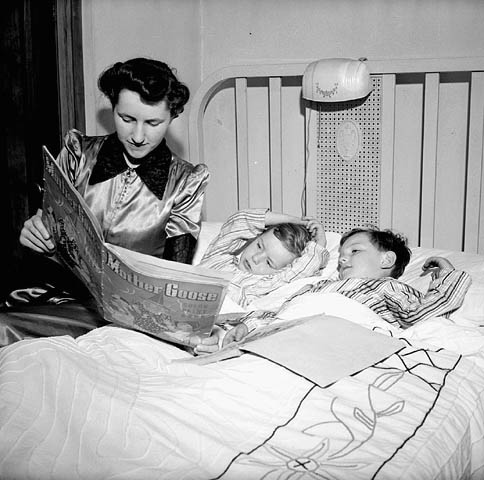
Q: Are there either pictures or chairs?
A: No, there are no chairs or pictures.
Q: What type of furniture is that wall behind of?
A: The wall is behind the bed.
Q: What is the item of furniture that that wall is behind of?
A: The piece of furniture is a bed.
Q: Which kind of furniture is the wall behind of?
A: The wall is behind the bed.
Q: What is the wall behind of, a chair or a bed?
A: The wall is behind a bed.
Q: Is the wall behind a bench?
A: No, the wall is behind a bed.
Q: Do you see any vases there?
A: No, there are no vases.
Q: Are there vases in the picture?
A: No, there are no vases.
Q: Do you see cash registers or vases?
A: No, there are no vases or cash registers.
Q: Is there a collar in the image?
A: Yes, there is a collar.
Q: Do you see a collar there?
A: Yes, there is a collar.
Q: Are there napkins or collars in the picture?
A: Yes, there is a collar.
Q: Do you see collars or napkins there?
A: Yes, there is a collar.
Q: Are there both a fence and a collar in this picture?
A: No, there is a collar but no fences.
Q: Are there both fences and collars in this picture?
A: No, there is a collar but no fences.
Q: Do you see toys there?
A: No, there are no toys.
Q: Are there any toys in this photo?
A: No, there are no toys.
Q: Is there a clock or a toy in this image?
A: No, there are no toys or clocks.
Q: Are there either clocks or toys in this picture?
A: No, there are no toys or clocks.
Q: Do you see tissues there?
A: No, there are no tissues.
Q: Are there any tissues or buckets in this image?
A: No, there are no tissues or buckets.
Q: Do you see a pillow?
A: Yes, there is a pillow.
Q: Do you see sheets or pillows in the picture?
A: Yes, there is a pillow.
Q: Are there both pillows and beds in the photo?
A: Yes, there are both a pillow and a bed.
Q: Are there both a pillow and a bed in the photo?
A: Yes, there are both a pillow and a bed.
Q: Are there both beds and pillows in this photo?
A: Yes, there are both a pillow and a bed.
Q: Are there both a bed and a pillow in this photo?
A: Yes, there are both a pillow and a bed.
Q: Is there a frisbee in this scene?
A: No, there are no frisbees.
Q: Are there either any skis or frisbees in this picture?
A: No, there are no frisbees or skis.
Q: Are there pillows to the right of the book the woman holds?
A: Yes, there is a pillow to the right of the book.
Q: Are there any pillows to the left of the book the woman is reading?
A: No, the pillow is to the right of the book.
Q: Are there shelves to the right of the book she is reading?
A: No, there is a pillow to the right of the book.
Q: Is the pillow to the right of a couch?
A: No, the pillow is to the right of the book.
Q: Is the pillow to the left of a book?
A: No, the pillow is to the right of a book.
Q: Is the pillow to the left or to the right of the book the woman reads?
A: The pillow is to the right of the book.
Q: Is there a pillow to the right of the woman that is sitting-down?
A: Yes, there is a pillow to the right of the woman.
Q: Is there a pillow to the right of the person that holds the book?
A: Yes, there is a pillow to the right of the woman.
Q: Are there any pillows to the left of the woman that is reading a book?
A: No, the pillow is to the right of the woman.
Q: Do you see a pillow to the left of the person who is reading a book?
A: No, the pillow is to the right of the woman.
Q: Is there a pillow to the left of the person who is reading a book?
A: No, the pillow is to the right of the woman.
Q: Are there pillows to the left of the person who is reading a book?
A: No, the pillow is to the right of the woman.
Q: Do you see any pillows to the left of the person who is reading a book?
A: No, the pillow is to the right of the woman.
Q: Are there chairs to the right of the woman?
A: No, there is a pillow to the right of the woman.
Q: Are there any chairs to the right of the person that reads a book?
A: No, there is a pillow to the right of the woman.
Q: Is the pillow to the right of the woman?
A: Yes, the pillow is to the right of the woman.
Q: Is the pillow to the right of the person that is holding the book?
A: Yes, the pillow is to the right of the woman.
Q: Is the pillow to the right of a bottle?
A: No, the pillow is to the right of the woman.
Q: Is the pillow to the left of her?
A: No, the pillow is to the right of the woman.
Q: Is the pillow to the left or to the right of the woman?
A: The pillow is to the right of the woman.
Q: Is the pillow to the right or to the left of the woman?
A: The pillow is to the right of the woman.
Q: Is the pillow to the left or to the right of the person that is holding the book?
A: The pillow is to the right of the woman.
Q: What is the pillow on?
A: The pillow is on the bed.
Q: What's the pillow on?
A: The pillow is on the bed.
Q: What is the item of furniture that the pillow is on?
A: The piece of furniture is a bed.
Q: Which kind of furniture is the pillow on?
A: The pillow is on the bed.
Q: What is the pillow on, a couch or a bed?
A: The pillow is on a bed.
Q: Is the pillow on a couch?
A: No, the pillow is on a bed.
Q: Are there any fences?
A: No, there are no fences.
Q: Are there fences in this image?
A: No, there are no fences.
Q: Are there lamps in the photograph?
A: Yes, there is a lamp.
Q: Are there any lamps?
A: Yes, there is a lamp.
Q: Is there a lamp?
A: Yes, there is a lamp.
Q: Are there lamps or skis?
A: Yes, there is a lamp.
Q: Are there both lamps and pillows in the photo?
A: Yes, there are both a lamp and pillows.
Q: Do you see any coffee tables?
A: No, there are no coffee tables.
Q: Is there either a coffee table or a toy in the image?
A: No, there are no coffee tables or toys.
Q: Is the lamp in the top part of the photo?
A: Yes, the lamp is in the top of the image.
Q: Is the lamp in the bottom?
A: No, the lamp is in the top of the image.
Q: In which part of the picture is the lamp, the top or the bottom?
A: The lamp is in the top of the image.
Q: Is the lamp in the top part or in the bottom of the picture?
A: The lamp is in the top of the image.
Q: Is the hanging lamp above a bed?
A: Yes, the lamp is above a bed.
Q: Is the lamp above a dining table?
A: No, the lamp is above a bed.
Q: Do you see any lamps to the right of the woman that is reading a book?
A: Yes, there is a lamp to the right of the woman.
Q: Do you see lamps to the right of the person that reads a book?
A: Yes, there is a lamp to the right of the woman.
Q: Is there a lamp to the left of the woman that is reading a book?
A: No, the lamp is to the right of the woman.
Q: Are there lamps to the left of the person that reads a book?
A: No, the lamp is to the right of the woman.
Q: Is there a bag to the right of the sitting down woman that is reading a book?
A: No, there is a lamp to the right of the woman.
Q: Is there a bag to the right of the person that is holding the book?
A: No, there is a lamp to the right of the woman.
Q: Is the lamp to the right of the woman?
A: Yes, the lamp is to the right of the woman.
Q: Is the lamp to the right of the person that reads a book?
A: Yes, the lamp is to the right of the woman.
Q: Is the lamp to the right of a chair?
A: No, the lamp is to the right of the woman.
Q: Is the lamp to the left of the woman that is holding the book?
A: No, the lamp is to the right of the woman.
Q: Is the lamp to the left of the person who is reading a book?
A: No, the lamp is to the right of the woman.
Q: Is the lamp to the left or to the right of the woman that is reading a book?
A: The lamp is to the right of the woman.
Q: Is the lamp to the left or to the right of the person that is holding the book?
A: The lamp is to the right of the woman.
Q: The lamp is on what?
A: The lamp is on the bed.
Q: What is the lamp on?
A: The lamp is on the bed.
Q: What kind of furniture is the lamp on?
A: The lamp is on the bed.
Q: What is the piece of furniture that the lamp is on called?
A: The piece of furniture is a bed.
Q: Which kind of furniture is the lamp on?
A: The lamp is on the bed.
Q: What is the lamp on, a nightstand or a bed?
A: The lamp is on a bed.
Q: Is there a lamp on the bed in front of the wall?
A: Yes, there is a lamp on the bed.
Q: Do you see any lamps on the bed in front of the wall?
A: Yes, there is a lamp on the bed.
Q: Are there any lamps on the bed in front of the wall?
A: Yes, there is a lamp on the bed.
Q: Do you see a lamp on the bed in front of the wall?
A: Yes, there is a lamp on the bed.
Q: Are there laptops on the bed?
A: No, there is a lamp on the bed.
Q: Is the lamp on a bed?
A: Yes, the lamp is on a bed.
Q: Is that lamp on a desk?
A: No, the lamp is on a bed.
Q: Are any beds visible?
A: Yes, there is a bed.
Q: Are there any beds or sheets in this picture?
A: Yes, there is a bed.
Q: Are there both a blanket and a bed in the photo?
A: Yes, there are both a bed and a blanket.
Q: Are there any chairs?
A: No, there are no chairs.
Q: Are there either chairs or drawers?
A: No, there are no chairs or drawers.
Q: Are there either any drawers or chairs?
A: No, there are no chairs or drawers.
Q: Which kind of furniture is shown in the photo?
A: The furniture is a bed.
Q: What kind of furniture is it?
A: The piece of furniture is a bed.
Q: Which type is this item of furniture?
A: This is a bed.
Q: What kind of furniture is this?
A: This is a bed.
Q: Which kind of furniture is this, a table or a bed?
A: This is a bed.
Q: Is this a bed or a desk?
A: This is a bed.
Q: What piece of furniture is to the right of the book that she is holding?
A: The piece of furniture is a bed.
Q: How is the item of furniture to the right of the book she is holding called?
A: The piece of furniture is a bed.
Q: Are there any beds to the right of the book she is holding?
A: Yes, there is a bed to the right of the book.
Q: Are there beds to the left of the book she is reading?
A: No, the bed is to the right of the book.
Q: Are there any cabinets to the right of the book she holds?
A: No, there is a bed to the right of the book.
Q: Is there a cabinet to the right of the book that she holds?
A: No, there is a bed to the right of the book.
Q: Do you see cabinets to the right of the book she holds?
A: No, there is a bed to the right of the book.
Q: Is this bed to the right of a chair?
A: No, the bed is to the right of the book.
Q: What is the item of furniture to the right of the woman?
A: The piece of furniture is a bed.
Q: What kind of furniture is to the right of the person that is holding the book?
A: The piece of furniture is a bed.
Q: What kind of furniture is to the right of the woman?
A: The piece of furniture is a bed.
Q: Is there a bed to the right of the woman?
A: Yes, there is a bed to the right of the woman.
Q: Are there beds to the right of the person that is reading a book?
A: Yes, there is a bed to the right of the woman.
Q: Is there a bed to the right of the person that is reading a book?
A: Yes, there is a bed to the right of the woman.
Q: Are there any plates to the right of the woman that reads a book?
A: No, there is a bed to the right of the woman.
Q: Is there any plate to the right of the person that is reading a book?
A: No, there is a bed to the right of the woman.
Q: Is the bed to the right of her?
A: Yes, the bed is to the right of the woman.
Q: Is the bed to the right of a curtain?
A: No, the bed is to the right of the woman.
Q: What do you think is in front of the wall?
A: The bed is in front of the wall.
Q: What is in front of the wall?
A: The bed is in front of the wall.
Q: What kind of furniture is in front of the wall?
A: The piece of furniture is a bed.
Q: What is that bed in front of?
A: The bed is in front of the wall.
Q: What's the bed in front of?
A: The bed is in front of the wall.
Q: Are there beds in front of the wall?
A: Yes, there is a bed in front of the wall.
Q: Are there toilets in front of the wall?
A: No, there is a bed in front of the wall.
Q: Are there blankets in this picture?
A: Yes, there is a blanket.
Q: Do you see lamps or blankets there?
A: Yes, there is a blanket.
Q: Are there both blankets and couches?
A: No, there is a blanket but no couches.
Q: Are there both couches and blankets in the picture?
A: No, there is a blanket but no couches.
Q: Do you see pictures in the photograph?
A: No, there are no pictures.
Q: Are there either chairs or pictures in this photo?
A: No, there are no pictures or chairs.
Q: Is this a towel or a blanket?
A: This is a blanket.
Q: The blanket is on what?
A: The blanket is on the bed.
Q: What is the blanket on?
A: The blanket is on the bed.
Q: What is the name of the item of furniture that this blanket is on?
A: The piece of furniture is a bed.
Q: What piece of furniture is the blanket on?
A: The blanket is on the bed.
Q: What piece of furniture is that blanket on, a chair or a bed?
A: The blanket is on a bed.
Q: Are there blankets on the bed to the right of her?
A: Yes, there is a blanket on the bed.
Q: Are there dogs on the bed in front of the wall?
A: No, there is a blanket on the bed.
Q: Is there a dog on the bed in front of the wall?
A: No, there is a blanket on the bed.